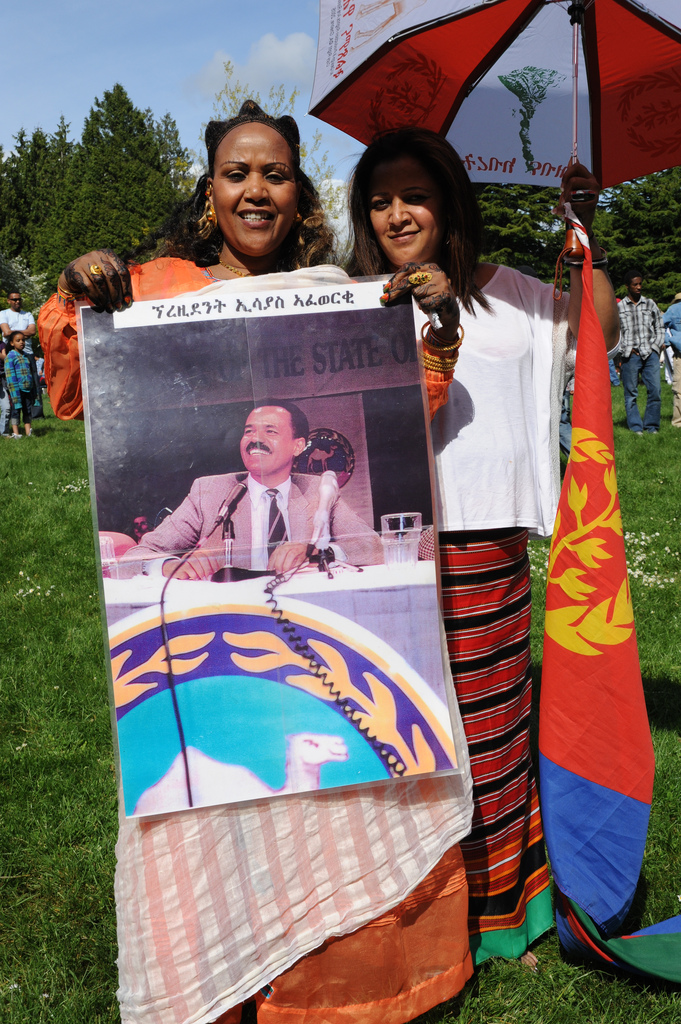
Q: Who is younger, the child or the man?
A: The child is younger than the man.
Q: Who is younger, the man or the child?
A: The child is younger than the man.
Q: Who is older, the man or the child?
A: The man is older than the child.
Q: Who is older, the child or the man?
A: The man is older than the child.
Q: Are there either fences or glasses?
A: No, there are no glasses or fences.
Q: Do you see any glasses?
A: No, there are no glasses.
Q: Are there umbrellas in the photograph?
A: Yes, there is an umbrella.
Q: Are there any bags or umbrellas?
A: Yes, there is an umbrella.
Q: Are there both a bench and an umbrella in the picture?
A: No, there is an umbrella but no benches.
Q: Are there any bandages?
A: No, there are no bandages.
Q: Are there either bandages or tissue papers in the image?
A: No, there are no bandages or tissue papers.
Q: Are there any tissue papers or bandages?
A: No, there are no bandages or tissue papers.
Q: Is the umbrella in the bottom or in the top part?
A: The umbrella is in the top of the image.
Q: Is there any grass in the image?
A: Yes, there is grass.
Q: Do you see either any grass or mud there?
A: Yes, there is grass.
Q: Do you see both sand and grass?
A: No, there is grass but no sand.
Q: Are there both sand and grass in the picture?
A: No, there is grass but no sand.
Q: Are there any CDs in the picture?
A: No, there are no cds.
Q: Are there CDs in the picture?
A: No, there are no cds.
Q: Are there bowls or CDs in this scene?
A: No, there are no CDs or bowls.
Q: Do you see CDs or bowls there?
A: No, there are no CDs or bowls.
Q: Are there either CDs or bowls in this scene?
A: No, there are no CDs or bowls.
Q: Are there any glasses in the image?
A: No, there are no glasses.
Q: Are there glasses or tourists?
A: No, there are no glasses or tourists.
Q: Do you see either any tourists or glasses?
A: No, there are no glasses or tourists.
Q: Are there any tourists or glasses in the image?
A: No, there are no glasses or tourists.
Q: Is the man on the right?
A: Yes, the man is on the right of the image.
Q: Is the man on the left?
A: No, the man is on the right of the image.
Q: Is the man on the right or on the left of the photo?
A: The man is on the right of the image.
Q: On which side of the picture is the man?
A: The man is on the right of the image.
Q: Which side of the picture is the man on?
A: The man is on the right of the image.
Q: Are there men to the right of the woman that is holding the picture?
A: Yes, there is a man to the right of the woman.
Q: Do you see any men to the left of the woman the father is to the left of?
A: No, the man is to the right of the woman.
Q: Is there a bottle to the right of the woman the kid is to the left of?
A: No, there is a man to the right of the woman.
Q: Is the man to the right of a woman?
A: Yes, the man is to the right of a woman.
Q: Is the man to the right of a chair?
A: No, the man is to the right of a woman.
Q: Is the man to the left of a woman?
A: No, the man is to the right of a woman.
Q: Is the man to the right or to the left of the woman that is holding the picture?
A: The man is to the right of the woman.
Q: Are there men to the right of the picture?
A: Yes, there is a man to the right of the picture.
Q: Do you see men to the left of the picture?
A: No, the man is to the right of the picture.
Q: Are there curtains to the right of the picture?
A: No, there is a man to the right of the picture.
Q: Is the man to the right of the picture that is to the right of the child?
A: Yes, the man is to the right of the picture.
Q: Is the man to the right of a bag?
A: No, the man is to the right of the picture.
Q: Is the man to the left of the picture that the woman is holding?
A: No, the man is to the right of the picture.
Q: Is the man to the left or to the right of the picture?
A: The man is to the right of the picture.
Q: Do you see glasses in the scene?
A: No, there are no glasses.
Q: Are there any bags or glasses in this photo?
A: No, there are no glasses or bags.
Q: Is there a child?
A: Yes, there is a child.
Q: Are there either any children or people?
A: Yes, there is a child.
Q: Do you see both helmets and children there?
A: No, there is a child but no helmets.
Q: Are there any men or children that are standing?
A: Yes, the child is standing.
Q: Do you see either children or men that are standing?
A: Yes, the child is standing.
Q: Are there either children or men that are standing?
A: Yes, the child is standing.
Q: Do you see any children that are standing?
A: Yes, there is a child that is standing.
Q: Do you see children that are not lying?
A: Yes, there is a child that is standing .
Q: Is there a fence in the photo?
A: No, there are no fences.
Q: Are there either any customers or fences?
A: No, there are no fences or customers.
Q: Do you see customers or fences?
A: No, there are no fences or customers.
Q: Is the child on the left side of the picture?
A: Yes, the child is on the left of the image.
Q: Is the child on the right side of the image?
A: No, the child is on the left of the image.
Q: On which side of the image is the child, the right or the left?
A: The child is on the left of the image.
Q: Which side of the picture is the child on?
A: The child is on the left of the image.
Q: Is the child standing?
A: Yes, the child is standing.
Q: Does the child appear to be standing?
A: Yes, the child is standing.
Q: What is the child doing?
A: The child is standing.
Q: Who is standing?
A: The kid is standing.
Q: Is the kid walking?
A: No, the kid is standing.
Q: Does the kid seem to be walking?
A: No, the kid is standing.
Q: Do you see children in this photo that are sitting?
A: No, there is a child but he is standing.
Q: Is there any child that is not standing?
A: No, there is a child but he is standing.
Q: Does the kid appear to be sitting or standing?
A: The kid is standing.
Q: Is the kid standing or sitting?
A: The kid is standing.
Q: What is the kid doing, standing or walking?
A: The kid is standing.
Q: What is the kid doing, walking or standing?
A: The kid is standing.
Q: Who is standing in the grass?
A: The kid is standing in the grass.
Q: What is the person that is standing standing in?
A: The child is standing in the grass.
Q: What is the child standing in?
A: The child is standing in the grass.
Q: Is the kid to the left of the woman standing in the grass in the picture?
A: Yes, the child is standing in the grass.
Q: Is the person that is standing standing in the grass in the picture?
A: Yes, the child is standing in the grass.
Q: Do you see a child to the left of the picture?
A: Yes, there is a child to the left of the picture.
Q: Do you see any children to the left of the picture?
A: Yes, there is a child to the left of the picture.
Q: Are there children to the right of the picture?
A: No, the child is to the left of the picture.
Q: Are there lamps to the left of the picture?
A: No, there is a child to the left of the picture.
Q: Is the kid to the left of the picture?
A: Yes, the kid is to the left of the picture.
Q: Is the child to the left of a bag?
A: No, the child is to the left of the picture.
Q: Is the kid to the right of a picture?
A: No, the kid is to the left of a picture.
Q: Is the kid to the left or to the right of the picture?
A: The kid is to the left of the picture.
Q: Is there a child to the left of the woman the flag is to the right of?
A: Yes, there is a child to the left of the woman.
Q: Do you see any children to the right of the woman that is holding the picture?
A: No, the child is to the left of the woman.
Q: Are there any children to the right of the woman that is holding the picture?
A: No, the child is to the left of the woman.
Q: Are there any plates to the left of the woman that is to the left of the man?
A: No, there is a child to the left of the woman.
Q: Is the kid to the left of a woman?
A: Yes, the kid is to the left of a woman.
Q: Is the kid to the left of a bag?
A: No, the kid is to the left of a woman.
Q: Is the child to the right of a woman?
A: No, the child is to the left of a woman.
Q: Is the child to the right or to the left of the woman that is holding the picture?
A: The child is to the left of the woman.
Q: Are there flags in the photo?
A: Yes, there is a flag.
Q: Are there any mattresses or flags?
A: Yes, there is a flag.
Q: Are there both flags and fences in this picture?
A: No, there is a flag but no fences.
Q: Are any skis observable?
A: No, there are no skis.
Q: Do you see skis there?
A: No, there are no skis.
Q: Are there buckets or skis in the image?
A: No, there are no skis or buckets.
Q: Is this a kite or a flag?
A: This is a flag.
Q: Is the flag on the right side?
A: Yes, the flag is on the right of the image.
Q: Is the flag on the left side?
A: No, the flag is on the right of the image.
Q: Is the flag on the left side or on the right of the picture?
A: The flag is on the right of the image.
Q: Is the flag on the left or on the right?
A: The flag is on the right of the image.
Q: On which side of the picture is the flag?
A: The flag is on the right of the image.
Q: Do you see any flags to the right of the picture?
A: Yes, there is a flag to the right of the picture.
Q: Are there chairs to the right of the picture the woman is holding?
A: No, there is a flag to the right of the picture.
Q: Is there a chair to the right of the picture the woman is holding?
A: No, there is a flag to the right of the picture.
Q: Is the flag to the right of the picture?
A: Yes, the flag is to the right of the picture.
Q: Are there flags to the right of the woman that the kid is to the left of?
A: Yes, there is a flag to the right of the woman.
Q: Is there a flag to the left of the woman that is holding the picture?
A: No, the flag is to the right of the woman.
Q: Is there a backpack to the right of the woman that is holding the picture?
A: No, there is a flag to the right of the woman.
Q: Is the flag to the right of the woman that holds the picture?
A: Yes, the flag is to the right of the woman.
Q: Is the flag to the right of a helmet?
A: No, the flag is to the right of the woman.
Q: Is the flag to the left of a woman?
A: No, the flag is to the right of a woman.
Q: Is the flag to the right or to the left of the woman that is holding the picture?
A: The flag is to the right of the woman.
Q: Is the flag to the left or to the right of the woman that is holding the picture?
A: The flag is to the right of the woman.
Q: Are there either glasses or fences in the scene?
A: No, there are no glasses or fences.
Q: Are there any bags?
A: No, there are no bags.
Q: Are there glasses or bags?
A: No, there are no bags or glasses.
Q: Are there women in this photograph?
A: Yes, there is a woman.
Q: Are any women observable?
A: Yes, there is a woman.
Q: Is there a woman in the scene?
A: Yes, there is a woman.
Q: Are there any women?
A: Yes, there is a woman.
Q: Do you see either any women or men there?
A: Yes, there is a woman.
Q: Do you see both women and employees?
A: No, there is a woman but no employees.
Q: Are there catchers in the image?
A: No, there are no catchers.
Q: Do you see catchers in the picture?
A: No, there are no catchers.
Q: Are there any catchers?
A: No, there are no catchers.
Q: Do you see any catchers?
A: No, there are no catchers.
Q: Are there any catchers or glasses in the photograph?
A: No, there are no catchers or glasses.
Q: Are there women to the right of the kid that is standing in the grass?
A: Yes, there is a woman to the right of the child.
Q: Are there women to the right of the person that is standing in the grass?
A: Yes, there is a woman to the right of the child.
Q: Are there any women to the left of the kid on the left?
A: No, the woman is to the right of the kid.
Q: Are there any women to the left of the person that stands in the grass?
A: No, the woman is to the right of the kid.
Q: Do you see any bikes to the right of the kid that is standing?
A: No, there is a woman to the right of the kid.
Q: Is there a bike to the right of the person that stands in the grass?
A: No, there is a woman to the right of the kid.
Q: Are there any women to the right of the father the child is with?
A: Yes, there is a woman to the right of the dad.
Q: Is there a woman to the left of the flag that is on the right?
A: Yes, there is a woman to the left of the flag.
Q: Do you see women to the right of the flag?
A: No, the woman is to the left of the flag.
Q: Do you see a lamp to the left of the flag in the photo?
A: No, there is a woman to the left of the flag.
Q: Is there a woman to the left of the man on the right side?
A: Yes, there is a woman to the left of the man.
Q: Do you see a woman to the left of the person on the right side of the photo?
A: Yes, there is a woman to the left of the man.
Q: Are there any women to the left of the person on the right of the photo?
A: Yes, there is a woman to the left of the man.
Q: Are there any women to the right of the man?
A: No, the woman is to the left of the man.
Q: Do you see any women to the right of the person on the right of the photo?
A: No, the woman is to the left of the man.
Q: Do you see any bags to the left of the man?
A: No, there is a woman to the left of the man.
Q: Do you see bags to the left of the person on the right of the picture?
A: No, there is a woman to the left of the man.